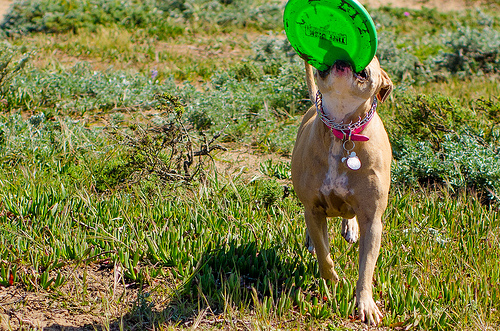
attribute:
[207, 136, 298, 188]
lines — grey